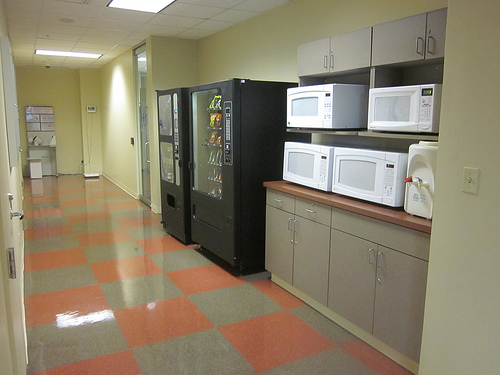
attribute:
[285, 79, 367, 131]
microwave — 4, white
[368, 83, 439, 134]
microwave — different, white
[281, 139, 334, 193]
microwave — white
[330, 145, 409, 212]
microwave — white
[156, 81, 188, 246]
vending machine — black, standing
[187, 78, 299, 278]
vending machine — standing, black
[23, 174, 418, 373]
floor — shiny, checkered, gray, orange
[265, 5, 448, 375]
cabinets — gray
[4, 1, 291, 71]
tiles — white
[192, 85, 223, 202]
door — glass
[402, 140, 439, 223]
dispenser — beverage, water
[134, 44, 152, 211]
door — clear, glass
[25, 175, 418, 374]
tiles — large, orange, gray, tan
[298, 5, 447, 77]
cabinets — hanging, small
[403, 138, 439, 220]
water cooler — white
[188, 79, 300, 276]
candy machine — black